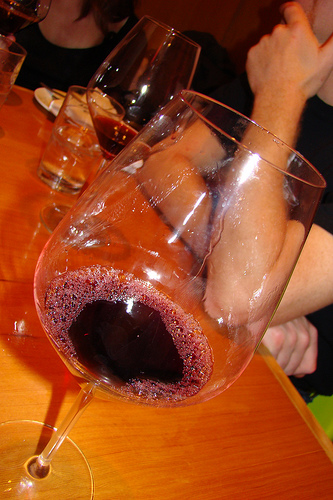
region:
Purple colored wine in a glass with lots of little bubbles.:
[40, 264, 214, 406]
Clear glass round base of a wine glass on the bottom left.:
[1, 417, 93, 497]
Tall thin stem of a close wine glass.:
[34, 381, 95, 469]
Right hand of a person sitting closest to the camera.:
[258, 312, 317, 378]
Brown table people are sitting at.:
[0, 76, 330, 495]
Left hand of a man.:
[241, 0, 327, 96]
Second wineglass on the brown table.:
[41, 13, 200, 260]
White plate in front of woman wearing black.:
[32, 84, 120, 131]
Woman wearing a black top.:
[6, 0, 149, 102]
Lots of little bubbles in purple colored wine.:
[60, 274, 92, 299]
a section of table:
[176, 421, 224, 462]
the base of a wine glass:
[0, 408, 120, 498]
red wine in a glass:
[87, 299, 171, 373]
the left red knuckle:
[271, 325, 286, 349]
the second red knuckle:
[284, 325, 303, 351]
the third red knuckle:
[297, 325, 314, 347]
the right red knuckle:
[302, 323, 328, 344]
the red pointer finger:
[293, 319, 321, 385]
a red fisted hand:
[254, 313, 324, 387]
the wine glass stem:
[34, 356, 112, 469]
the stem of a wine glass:
[29, 386, 97, 474]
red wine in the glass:
[41, 262, 216, 406]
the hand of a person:
[256, 313, 323, 380]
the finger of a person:
[276, 1, 313, 30]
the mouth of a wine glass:
[174, 89, 330, 193]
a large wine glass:
[0, 84, 326, 498]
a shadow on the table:
[1, 264, 92, 456]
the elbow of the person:
[197, 286, 256, 341]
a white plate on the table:
[30, 83, 119, 130]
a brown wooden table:
[0, 78, 332, 499]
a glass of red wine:
[14, 90, 323, 491]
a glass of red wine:
[43, 10, 206, 252]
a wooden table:
[2, 62, 326, 496]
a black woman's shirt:
[1, 20, 142, 82]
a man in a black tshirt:
[133, 2, 330, 397]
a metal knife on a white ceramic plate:
[39, 79, 124, 125]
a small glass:
[27, 88, 126, 195]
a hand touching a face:
[235, 2, 331, 117]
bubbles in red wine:
[27, 257, 238, 401]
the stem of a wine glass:
[10, 375, 128, 498]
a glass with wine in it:
[0, 88, 324, 497]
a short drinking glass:
[37, 85, 103, 187]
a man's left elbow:
[202, 0, 330, 325]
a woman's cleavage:
[39, 0, 105, 47]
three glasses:
[2, 15, 330, 494]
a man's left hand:
[246, 0, 329, 103]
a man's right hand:
[264, 313, 316, 375]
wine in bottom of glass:
[42, 263, 214, 404]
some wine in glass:
[92, 116, 136, 160]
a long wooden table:
[2, 95, 331, 497]